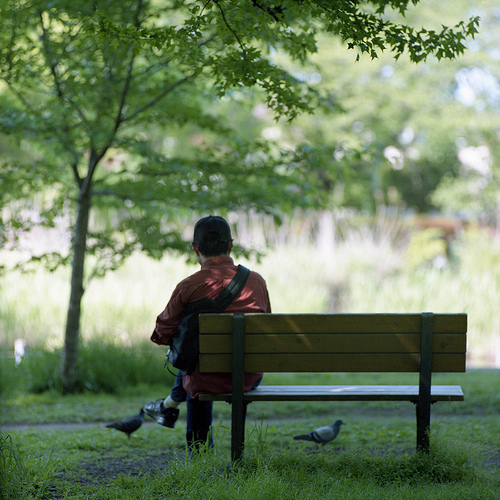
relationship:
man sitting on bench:
[150, 215, 270, 449] [195, 306, 465, 470]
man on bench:
[150, 215, 270, 449] [195, 306, 465, 470]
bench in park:
[194, 309, 467, 458] [0, 0, 497, 498]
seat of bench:
[212, 383, 463, 403] [195, 306, 465, 470]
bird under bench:
[294, 420, 339, 453] [195, 306, 465, 470]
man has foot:
[142, 215, 270, 467] [139, 397, 178, 427]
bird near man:
[105, 407, 148, 437] [142, 215, 270, 467]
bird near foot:
[105, 407, 148, 437] [139, 397, 178, 427]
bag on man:
[164, 264, 251, 368] [142, 215, 270, 467]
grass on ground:
[128, 422, 277, 498] [0, 357, 493, 498]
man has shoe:
[150, 215, 270, 449] [141, 399, 181, 429]